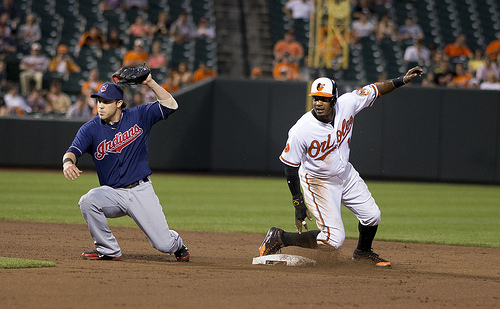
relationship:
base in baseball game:
[263, 254, 307, 267] [25, 13, 492, 308]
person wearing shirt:
[126, 38, 146, 63] [130, 55, 140, 59]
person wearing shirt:
[278, 34, 299, 60] [290, 50, 294, 53]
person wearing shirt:
[57, 45, 76, 76] [448, 46, 461, 56]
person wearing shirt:
[192, 63, 214, 78] [84, 36, 92, 42]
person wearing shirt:
[276, 53, 300, 77] [30, 59, 40, 69]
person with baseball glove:
[68, 86, 191, 260] [117, 67, 153, 83]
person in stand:
[192, 63, 214, 78] [36, 7, 462, 56]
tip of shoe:
[384, 263, 387, 266] [359, 250, 383, 265]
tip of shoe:
[184, 257, 188, 260] [177, 255, 189, 261]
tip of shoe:
[84, 256, 90, 261] [263, 226, 285, 256]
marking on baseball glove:
[114, 78, 118, 81] [117, 67, 153, 83]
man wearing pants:
[90, 188, 165, 247] [92, 192, 148, 211]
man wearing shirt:
[90, 188, 165, 247] [312, 128, 343, 165]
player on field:
[68, 86, 191, 260] [188, 181, 260, 224]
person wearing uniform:
[287, 119, 378, 237] [309, 175, 342, 196]